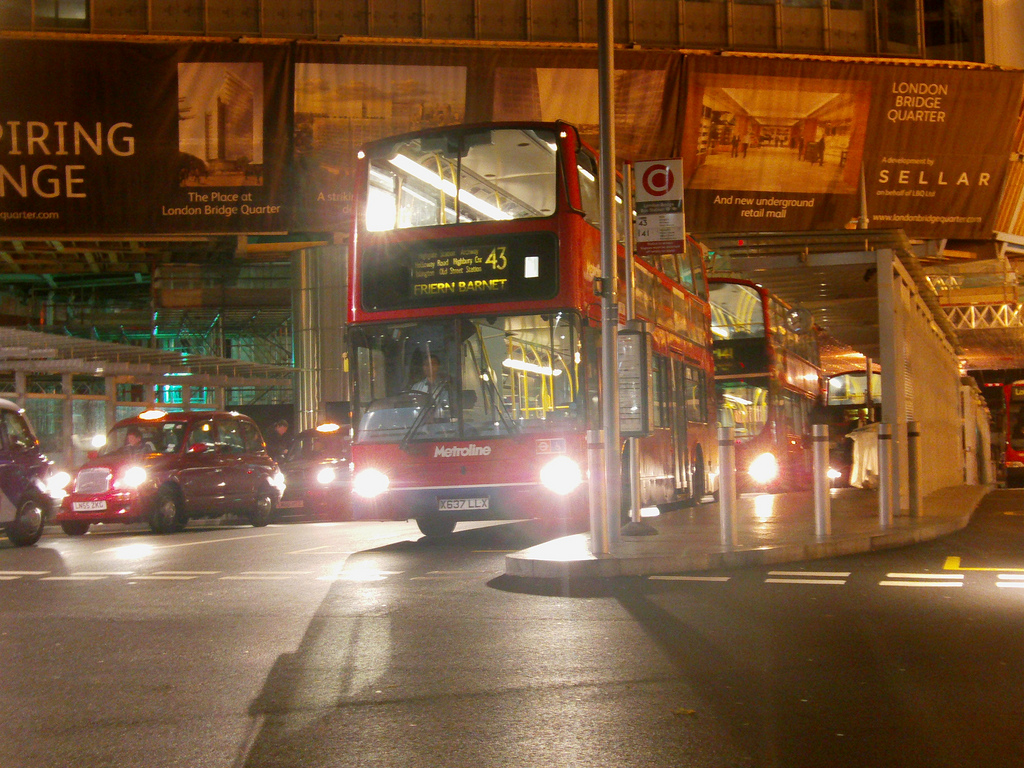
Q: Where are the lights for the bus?
A: On the front.